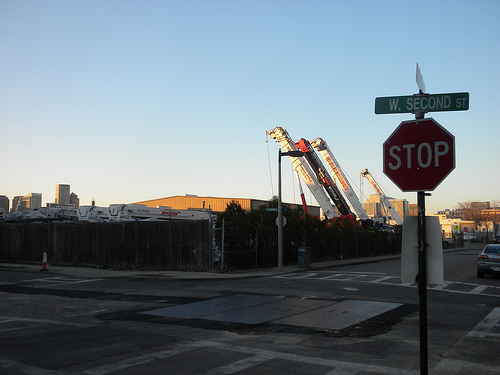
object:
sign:
[373, 91, 468, 114]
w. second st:
[386, 95, 470, 111]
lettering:
[388, 141, 451, 172]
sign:
[381, 118, 457, 193]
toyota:
[475, 243, 500, 280]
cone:
[40, 248, 52, 272]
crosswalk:
[269, 266, 500, 298]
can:
[295, 244, 314, 270]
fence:
[0, 217, 402, 272]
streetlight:
[275, 147, 305, 271]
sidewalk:
[0, 254, 403, 281]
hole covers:
[271, 294, 406, 333]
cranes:
[267, 127, 402, 254]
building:
[127, 192, 321, 228]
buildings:
[54, 183, 79, 205]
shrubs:
[218, 201, 262, 271]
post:
[414, 191, 429, 375]